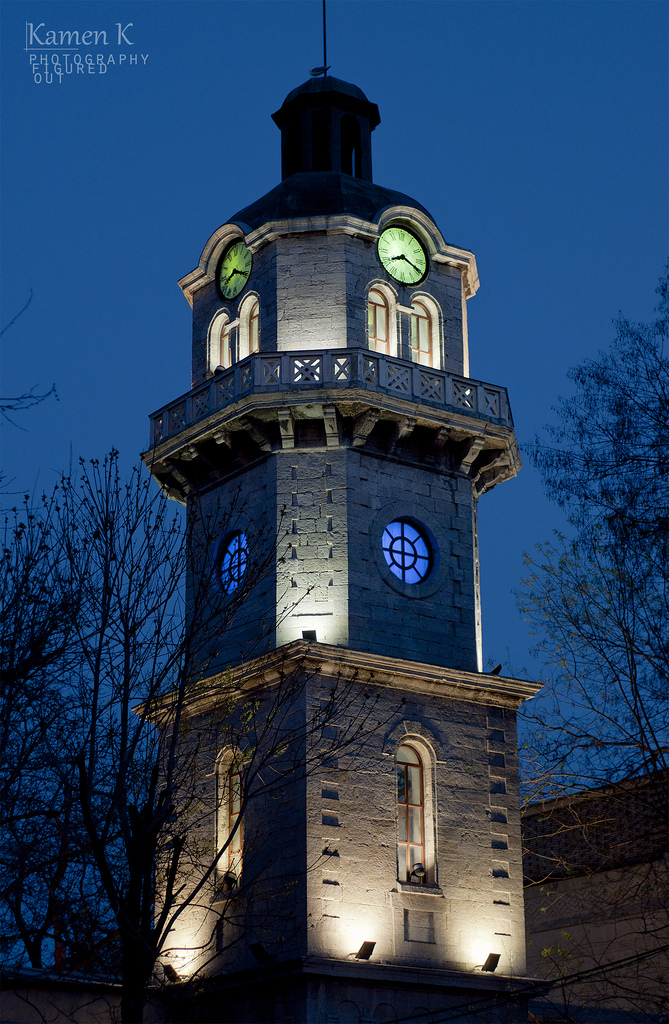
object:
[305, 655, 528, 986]
wall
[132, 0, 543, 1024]
building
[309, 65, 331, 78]
bird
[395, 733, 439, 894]
window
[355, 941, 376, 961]
light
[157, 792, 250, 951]
branches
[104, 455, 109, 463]
leaves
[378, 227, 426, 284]
face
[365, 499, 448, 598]
window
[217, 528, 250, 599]
window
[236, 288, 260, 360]
window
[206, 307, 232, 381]
window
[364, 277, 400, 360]
window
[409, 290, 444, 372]
window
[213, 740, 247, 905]
window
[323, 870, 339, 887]
square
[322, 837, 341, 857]
square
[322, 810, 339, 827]
square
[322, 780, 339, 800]
square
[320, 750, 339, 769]
square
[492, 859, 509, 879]
square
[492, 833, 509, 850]
square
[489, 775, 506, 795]
square